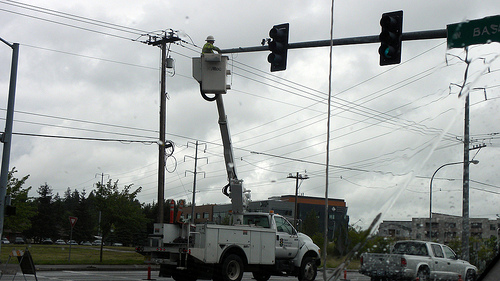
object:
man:
[201, 35, 222, 58]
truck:
[135, 54, 320, 281]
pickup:
[359, 239, 479, 280]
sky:
[0, 0, 500, 236]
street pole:
[157, 45, 166, 223]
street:
[0, 269, 500, 281]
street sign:
[447, 14, 500, 50]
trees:
[0, 167, 145, 246]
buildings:
[150, 194, 348, 254]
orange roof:
[280, 196, 347, 207]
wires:
[0, 9, 141, 43]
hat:
[205, 35, 215, 40]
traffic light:
[377, 10, 403, 67]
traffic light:
[267, 23, 288, 72]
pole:
[218, 29, 448, 54]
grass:
[0, 246, 142, 265]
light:
[380, 45, 393, 57]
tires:
[300, 259, 318, 281]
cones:
[145, 254, 152, 275]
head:
[204, 36, 216, 44]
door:
[274, 217, 297, 258]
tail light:
[398, 257, 406, 265]